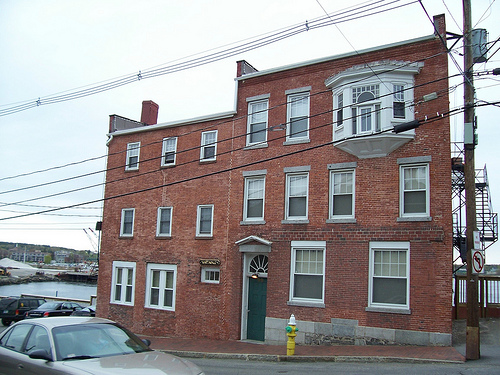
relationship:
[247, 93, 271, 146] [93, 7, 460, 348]
window on building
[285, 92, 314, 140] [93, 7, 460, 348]
window on building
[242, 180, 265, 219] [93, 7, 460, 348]
window on building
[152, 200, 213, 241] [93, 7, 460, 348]
windows on building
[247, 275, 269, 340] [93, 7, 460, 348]
door on building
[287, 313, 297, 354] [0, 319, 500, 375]
fire hydrant on road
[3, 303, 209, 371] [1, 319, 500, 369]
car on road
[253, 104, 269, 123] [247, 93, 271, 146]
lines on window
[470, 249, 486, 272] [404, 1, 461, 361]
sign on pole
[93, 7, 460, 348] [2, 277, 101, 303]
building beside sea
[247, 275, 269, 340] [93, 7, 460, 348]
door at building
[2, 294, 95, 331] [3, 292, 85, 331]
cars parked at side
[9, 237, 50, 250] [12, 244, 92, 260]
buildings near mountain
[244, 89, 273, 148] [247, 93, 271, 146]
frame on window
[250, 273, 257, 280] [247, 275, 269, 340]
light on door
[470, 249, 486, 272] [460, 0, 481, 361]
sign on pole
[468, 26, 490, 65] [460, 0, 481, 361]
transformer atop pole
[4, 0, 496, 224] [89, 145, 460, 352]
power lines near house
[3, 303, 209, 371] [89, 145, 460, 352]
car outside house